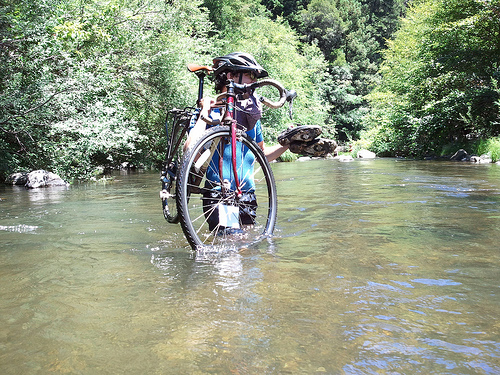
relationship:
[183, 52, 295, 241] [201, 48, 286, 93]
biker has grey helmet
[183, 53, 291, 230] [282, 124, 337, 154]
biker carries shoes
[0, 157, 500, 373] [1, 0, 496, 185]
river flows through forest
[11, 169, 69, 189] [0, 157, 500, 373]
rocks beside river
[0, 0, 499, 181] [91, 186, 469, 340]
forest beside river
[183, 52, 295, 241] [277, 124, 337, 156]
biker has shoes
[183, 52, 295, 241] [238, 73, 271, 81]
biker wearing glasses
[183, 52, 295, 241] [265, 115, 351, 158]
biker carrying shoes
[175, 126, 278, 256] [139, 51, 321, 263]
bike wheels of bike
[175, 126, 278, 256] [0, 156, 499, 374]
bike wheels in river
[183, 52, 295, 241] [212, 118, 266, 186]
biker wearing shirt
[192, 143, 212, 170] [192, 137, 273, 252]
reflector in spokes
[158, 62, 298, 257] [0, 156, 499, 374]
bicycle in river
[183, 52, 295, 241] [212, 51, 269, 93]
biker wearing grey helmet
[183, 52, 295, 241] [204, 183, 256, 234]
biker wearing pants